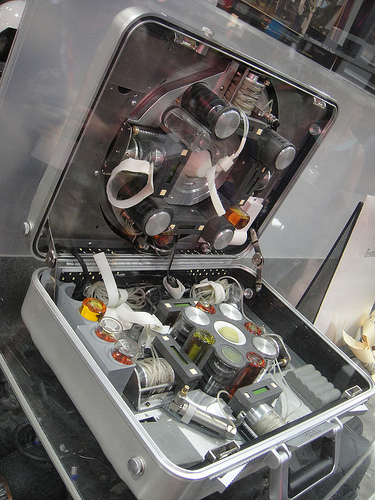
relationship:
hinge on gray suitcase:
[27, 213, 75, 310] [19, 4, 373, 498]